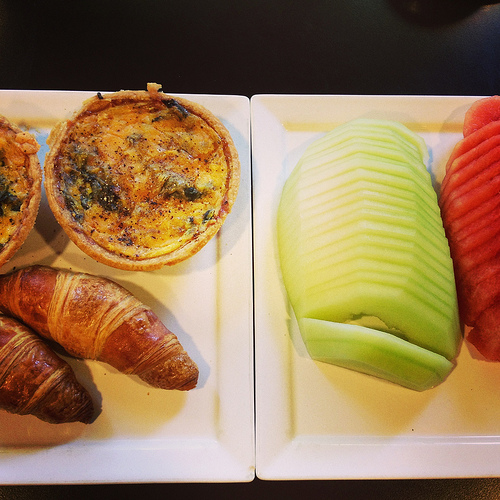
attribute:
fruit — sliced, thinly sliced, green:
[276, 118, 466, 393]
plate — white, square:
[248, 92, 499, 487]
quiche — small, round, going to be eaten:
[46, 92, 239, 273]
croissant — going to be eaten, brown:
[2, 263, 203, 391]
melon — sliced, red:
[436, 92, 500, 362]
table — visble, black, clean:
[2, 0, 499, 499]